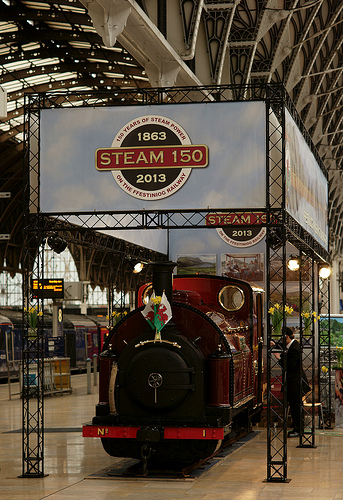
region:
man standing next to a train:
[267, 322, 310, 439]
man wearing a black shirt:
[265, 323, 307, 438]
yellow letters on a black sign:
[26, 275, 64, 298]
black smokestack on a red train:
[147, 259, 175, 300]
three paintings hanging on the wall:
[174, 251, 306, 278]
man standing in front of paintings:
[270, 324, 308, 435]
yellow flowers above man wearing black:
[267, 300, 293, 336]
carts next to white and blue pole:
[18, 356, 93, 397]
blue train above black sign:
[0, 306, 73, 373]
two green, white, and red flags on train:
[141, 287, 172, 341]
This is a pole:
[257, 201, 279, 489]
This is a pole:
[274, 211, 296, 498]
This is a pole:
[293, 240, 303, 472]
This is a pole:
[307, 251, 318, 462]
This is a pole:
[324, 268, 340, 452]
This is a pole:
[15, 213, 49, 495]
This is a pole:
[254, 226, 295, 496]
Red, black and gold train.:
[78, 253, 276, 476]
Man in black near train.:
[264, 319, 308, 443]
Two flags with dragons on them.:
[140, 285, 175, 340]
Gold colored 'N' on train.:
[93, 426, 106, 436]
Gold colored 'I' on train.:
[199, 426, 207, 436]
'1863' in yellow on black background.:
[135, 130, 170, 141]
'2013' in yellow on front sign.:
[133, 172, 169, 186]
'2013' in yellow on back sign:
[230, 230, 253, 237]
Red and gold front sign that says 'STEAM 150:
[95, 143, 207, 172]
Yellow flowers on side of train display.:
[269, 298, 342, 379]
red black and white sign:
[98, 113, 214, 219]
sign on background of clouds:
[105, 123, 231, 177]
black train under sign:
[100, 264, 216, 427]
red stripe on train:
[83, 414, 227, 459]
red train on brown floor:
[82, 265, 259, 475]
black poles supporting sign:
[17, 208, 41, 471]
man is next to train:
[261, 325, 320, 436]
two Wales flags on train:
[121, 280, 170, 340]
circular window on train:
[215, 278, 245, 320]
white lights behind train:
[286, 258, 342, 301]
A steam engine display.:
[17, 82, 325, 480]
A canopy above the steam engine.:
[20, 78, 328, 257]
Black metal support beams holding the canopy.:
[16, 205, 330, 477]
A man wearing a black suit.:
[266, 324, 308, 435]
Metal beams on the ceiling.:
[0, 0, 337, 245]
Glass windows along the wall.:
[0, 236, 175, 297]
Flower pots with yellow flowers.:
[262, 301, 336, 399]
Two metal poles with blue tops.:
[81, 349, 98, 391]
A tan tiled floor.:
[0, 365, 339, 496]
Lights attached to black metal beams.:
[28, 231, 331, 287]